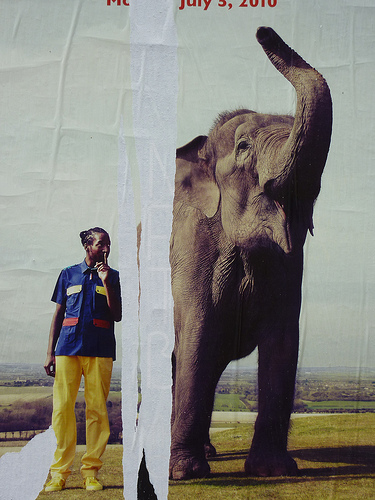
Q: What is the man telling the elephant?
A: Be Quiet.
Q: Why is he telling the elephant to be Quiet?
A: Because Elephants are very noisy.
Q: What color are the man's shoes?
A: Yellow.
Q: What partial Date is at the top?
A: July 2010.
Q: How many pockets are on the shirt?
A: 4.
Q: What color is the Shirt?
A: Blue.